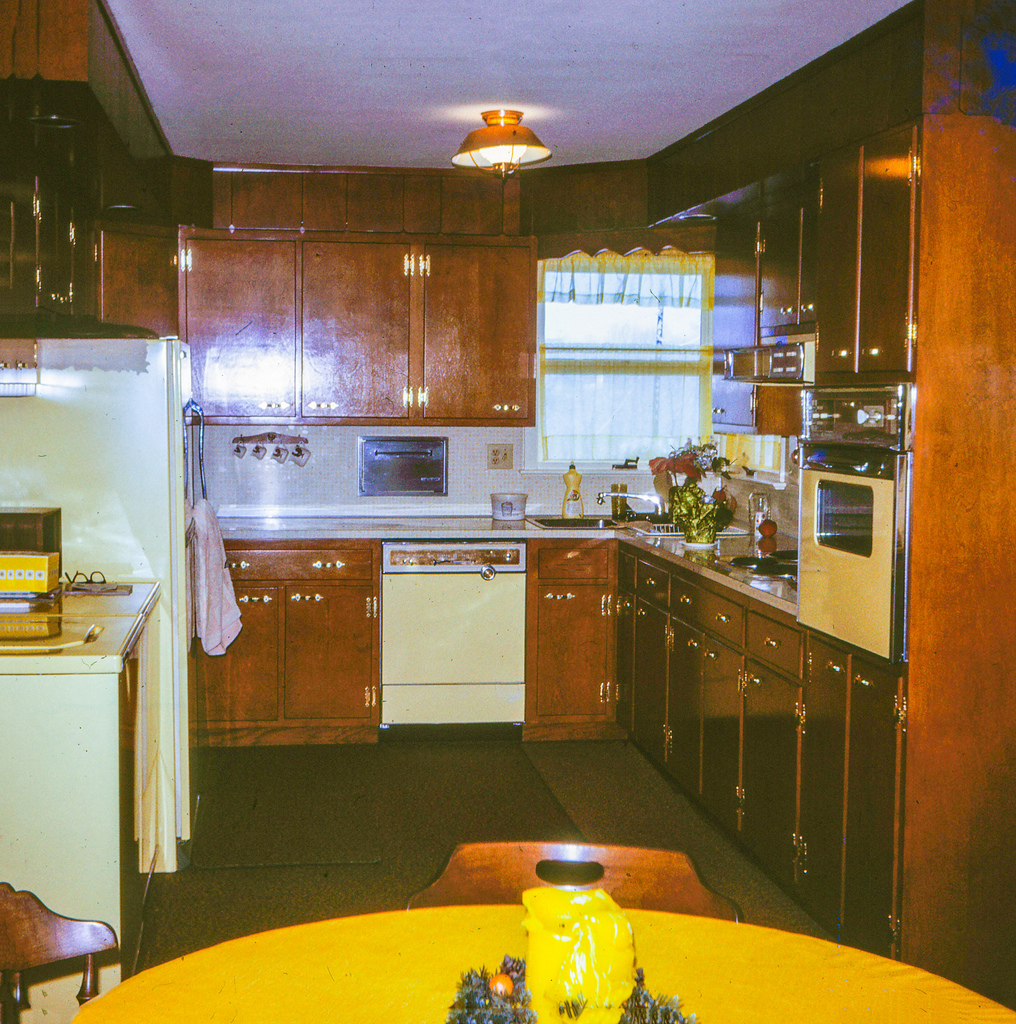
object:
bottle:
[563, 462, 583, 520]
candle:
[519, 884, 636, 1023]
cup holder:
[228, 432, 311, 467]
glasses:
[64, 570, 106, 583]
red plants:
[649, 457, 702, 484]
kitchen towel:
[194, 499, 244, 657]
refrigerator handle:
[184, 518, 195, 550]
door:
[356, 435, 447, 496]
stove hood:
[724, 345, 805, 383]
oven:
[797, 386, 914, 663]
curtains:
[536, 255, 716, 465]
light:
[452, 109, 554, 181]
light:
[202, 337, 330, 413]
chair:
[406, 840, 742, 923]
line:
[616, 539, 904, 963]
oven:
[381, 544, 525, 728]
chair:
[0, 882, 119, 1024]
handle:
[680, 594, 693, 607]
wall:
[192, 424, 526, 506]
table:
[66, 903, 1013, 1023]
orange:
[191, 792, 383, 868]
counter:
[0, 566, 163, 676]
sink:
[524, 517, 619, 530]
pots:
[649, 435, 738, 552]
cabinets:
[522, 537, 619, 742]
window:
[542, 273, 698, 464]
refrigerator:
[0, 336, 191, 875]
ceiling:
[81, 0, 930, 172]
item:
[445, 882, 690, 1024]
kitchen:
[0, 0, 1013, 1022]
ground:
[136, 741, 835, 972]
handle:
[714, 611, 730, 624]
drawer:
[692, 584, 747, 647]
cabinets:
[644, 58, 922, 387]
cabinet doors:
[178, 228, 409, 425]